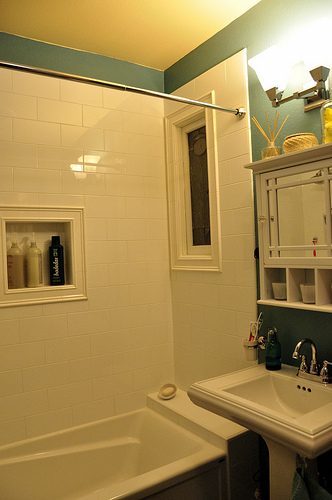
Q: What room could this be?
A: It is a bathroom.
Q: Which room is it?
A: It is a bathroom.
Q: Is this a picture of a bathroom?
A: Yes, it is showing a bathroom.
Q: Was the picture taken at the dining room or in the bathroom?
A: It was taken at the bathroom.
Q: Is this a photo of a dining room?
A: No, the picture is showing a bathroom.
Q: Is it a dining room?
A: No, it is a bathroom.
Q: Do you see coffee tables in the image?
A: No, there are no coffee tables.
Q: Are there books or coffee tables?
A: No, there are no coffee tables or books.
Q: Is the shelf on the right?
A: Yes, the shelf is on the right of the image.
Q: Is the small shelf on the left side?
A: No, the shelf is on the right of the image.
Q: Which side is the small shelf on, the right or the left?
A: The shelf is on the right of the image.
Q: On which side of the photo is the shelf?
A: The shelf is on the right of the image.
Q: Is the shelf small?
A: Yes, the shelf is small.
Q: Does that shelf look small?
A: Yes, the shelf is small.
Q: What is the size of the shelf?
A: The shelf is small.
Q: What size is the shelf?
A: The shelf is small.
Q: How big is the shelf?
A: The shelf is small.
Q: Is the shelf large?
A: No, the shelf is small.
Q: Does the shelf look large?
A: No, the shelf is small.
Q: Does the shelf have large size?
A: No, the shelf is small.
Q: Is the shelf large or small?
A: The shelf is small.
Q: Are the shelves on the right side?
A: Yes, the shelves are on the right of the image.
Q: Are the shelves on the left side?
A: No, the shelves are on the right of the image.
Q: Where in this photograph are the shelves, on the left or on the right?
A: The shelves are on the right of the image.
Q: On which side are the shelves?
A: The shelves are on the right of the image.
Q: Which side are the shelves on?
A: The shelves are on the right of the image.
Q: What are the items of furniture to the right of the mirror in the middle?
A: The pieces of furniture are shelves.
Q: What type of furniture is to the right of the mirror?
A: The pieces of furniture are shelves.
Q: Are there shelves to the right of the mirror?
A: Yes, there are shelves to the right of the mirror.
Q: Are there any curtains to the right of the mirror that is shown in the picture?
A: No, there are shelves to the right of the mirror.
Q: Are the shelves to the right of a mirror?
A: Yes, the shelves are to the right of a mirror.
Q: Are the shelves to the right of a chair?
A: No, the shelves are to the right of a mirror.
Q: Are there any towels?
A: Yes, there is a towel.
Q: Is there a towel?
A: Yes, there is a towel.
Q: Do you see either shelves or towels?
A: Yes, there is a towel.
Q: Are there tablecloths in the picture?
A: No, there are no tablecloths.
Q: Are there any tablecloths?
A: No, there are no tablecloths.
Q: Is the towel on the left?
A: No, the towel is on the right of the image.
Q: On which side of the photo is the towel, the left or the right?
A: The towel is on the right of the image.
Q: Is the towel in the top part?
A: No, the towel is in the bottom of the image.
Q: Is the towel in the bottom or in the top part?
A: The towel is in the bottom of the image.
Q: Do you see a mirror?
A: Yes, there is a mirror.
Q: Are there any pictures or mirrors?
A: Yes, there is a mirror.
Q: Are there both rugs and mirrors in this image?
A: No, there is a mirror but no rugs.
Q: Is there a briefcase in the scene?
A: No, there are no briefcases.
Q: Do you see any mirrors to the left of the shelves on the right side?
A: Yes, there is a mirror to the left of the shelves.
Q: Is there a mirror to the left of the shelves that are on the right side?
A: Yes, there is a mirror to the left of the shelves.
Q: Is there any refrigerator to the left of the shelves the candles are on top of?
A: No, there is a mirror to the left of the shelves.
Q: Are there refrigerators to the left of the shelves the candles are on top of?
A: No, there is a mirror to the left of the shelves.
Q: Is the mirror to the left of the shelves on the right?
A: Yes, the mirror is to the left of the shelves.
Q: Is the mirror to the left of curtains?
A: No, the mirror is to the left of the shelves.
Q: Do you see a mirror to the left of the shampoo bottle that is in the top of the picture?
A: Yes, there is a mirror to the left of the shampoo bottle.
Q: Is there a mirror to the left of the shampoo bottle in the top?
A: Yes, there is a mirror to the left of the shampoo bottle.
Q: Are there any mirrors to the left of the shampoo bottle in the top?
A: Yes, there is a mirror to the left of the shampoo bottle.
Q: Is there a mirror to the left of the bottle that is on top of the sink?
A: Yes, there is a mirror to the left of the shampoo bottle.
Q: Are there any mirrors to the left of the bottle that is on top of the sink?
A: Yes, there is a mirror to the left of the shampoo bottle.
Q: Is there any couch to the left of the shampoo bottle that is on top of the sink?
A: No, there is a mirror to the left of the shampoo bottle.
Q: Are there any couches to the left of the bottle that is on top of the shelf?
A: No, there is a mirror to the left of the shampoo bottle.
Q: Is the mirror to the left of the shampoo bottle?
A: Yes, the mirror is to the left of the shampoo bottle.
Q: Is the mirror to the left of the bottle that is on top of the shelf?
A: Yes, the mirror is to the left of the shampoo bottle.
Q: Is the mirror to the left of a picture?
A: No, the mirror is to the left of the shampoo bottle.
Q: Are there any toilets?
A: No, there are no toilets.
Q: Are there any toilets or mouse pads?
A: No, there are no toilets or mouse pads.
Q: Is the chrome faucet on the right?
A: Yes, the tap is on the right of the image.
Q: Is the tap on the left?
A: No, the tap is on the right of the image.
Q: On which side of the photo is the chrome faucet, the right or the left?
A: The faucet is on the right of the image.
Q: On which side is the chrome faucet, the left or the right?
A: The faucet is on the right of the image.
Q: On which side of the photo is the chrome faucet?
A: The faucet is on the right of the image.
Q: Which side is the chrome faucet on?
A: The faucet is on the right of the image.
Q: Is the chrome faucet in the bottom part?
A: Yes, the faucet is in the bottom of the image.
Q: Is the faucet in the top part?
A: No, the faucet is in the bottom of the image.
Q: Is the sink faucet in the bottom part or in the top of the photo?
A: The tap is in the bottom of the image.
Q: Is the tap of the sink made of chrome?
A: Yes, the faucet is made of chrome.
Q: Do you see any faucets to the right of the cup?
A: Yes, there is a faucet to the right of the cup.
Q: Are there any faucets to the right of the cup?
A: Yes, there is a faucet to the right of the cup.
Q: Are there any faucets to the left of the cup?
A: No, the faucet is to the right of the cup.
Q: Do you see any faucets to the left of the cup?
A: No, the faucet is to the right of the cup.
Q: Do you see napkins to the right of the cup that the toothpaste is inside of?
A: No, there is a faucet to the right of the cup.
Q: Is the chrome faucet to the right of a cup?
A: Yes, the tap is to the right of a cup.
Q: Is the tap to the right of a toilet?
A: No, the tap is to the right of a cup.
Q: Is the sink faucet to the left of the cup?
A: No, the faucet is to the right of the cup.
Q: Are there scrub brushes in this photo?
A: No, there are no scrub brushes.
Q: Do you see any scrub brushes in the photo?
A: No, there are no scrub brushes.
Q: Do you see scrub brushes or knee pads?
A: No, there are no scrub brushes or knee pads.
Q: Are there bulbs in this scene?
A: No, there are no bulbs.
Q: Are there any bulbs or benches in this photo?
A: No, there are no bulbs or benches.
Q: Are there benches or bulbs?
A: No, there are no bulbs or benches.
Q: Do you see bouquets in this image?
A: No, there are no bouquets.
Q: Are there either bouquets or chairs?
A: No, there are no bouquets or chairs.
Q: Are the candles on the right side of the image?
A: Yes, the candles are on the right of the image.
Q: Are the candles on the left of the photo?
A: No, the candles are on the right of the image.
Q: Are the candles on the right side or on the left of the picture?
A: The candles are on the right of the image.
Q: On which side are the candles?
A: The candles are on the right of the image.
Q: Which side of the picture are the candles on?
A: The candles are on the right of the image.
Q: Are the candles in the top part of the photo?
A: Yes, the candles are in the top of the image.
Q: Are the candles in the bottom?
A: No, the candles are in the top of the image.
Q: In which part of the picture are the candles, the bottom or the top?
A: The candles are in the top of the image.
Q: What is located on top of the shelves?
A: The candles are on top of the shelves.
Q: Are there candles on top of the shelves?
A: Yes, there are candles on top of the shelves.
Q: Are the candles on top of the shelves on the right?
A: Yes, the candles are on top of the shelves.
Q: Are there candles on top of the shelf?
A: Yes, there are candles on top of the shelf.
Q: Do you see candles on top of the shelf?
A: Yes, there are candles on top of the shelf.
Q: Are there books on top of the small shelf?
A: No, there are candles on top of the shelf.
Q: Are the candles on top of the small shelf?
A: Yes, the candles are on top of the shelf.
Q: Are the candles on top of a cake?
A: No, the candles are on top of the shelf.